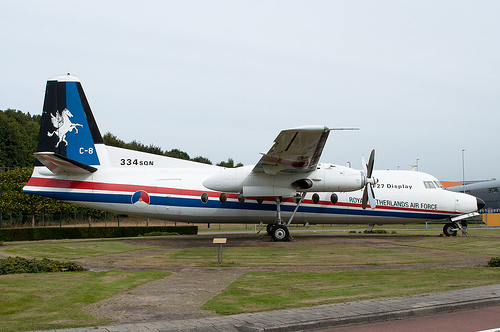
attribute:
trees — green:
[0, 109, 243, 221]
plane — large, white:
[20, 72, 487, 242]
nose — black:
[474, 196, 484, 212]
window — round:
[198, 190, 211, 208]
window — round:
[215, 188, 229, 207]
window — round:
[234, 192, 248, 209]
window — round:
[307, 190, 321, 209]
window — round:
[327, 191, 340, 210]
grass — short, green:
[0, 221, 498, 330]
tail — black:
[17, 76, 103, 179]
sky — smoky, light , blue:
[133, 50, 301, 102]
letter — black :
[385, 182, 392, 191]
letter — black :
[384, 181, 401, 191]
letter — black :
[391, 180, 403, 191]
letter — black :
[399, 177, 406, 190]